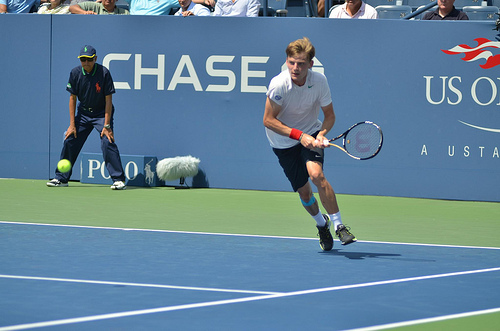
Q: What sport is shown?
A: Tennis.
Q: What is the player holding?
A: Tennis racquet.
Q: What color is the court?
A: Blue.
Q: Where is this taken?
A: Tennis match.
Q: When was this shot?
A: Daytime.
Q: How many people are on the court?
A: 2.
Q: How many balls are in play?
A: 1.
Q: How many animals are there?
A: 0.